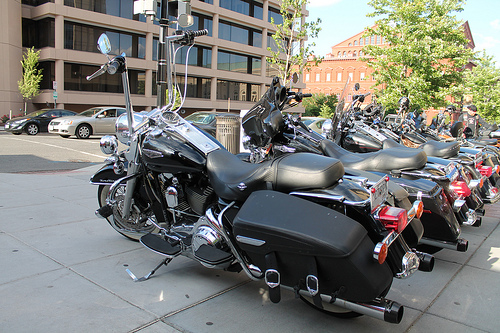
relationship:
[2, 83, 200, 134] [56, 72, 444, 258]
traffic on street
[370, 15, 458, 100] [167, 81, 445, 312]
tree above motorcycle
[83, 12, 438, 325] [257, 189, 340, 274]
motorcycle has compartment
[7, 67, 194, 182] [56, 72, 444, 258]
car across street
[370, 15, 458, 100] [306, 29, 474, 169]
tree in background